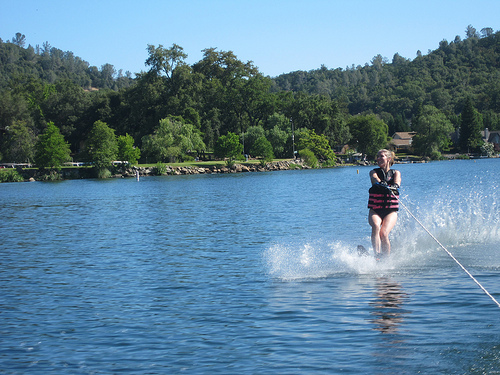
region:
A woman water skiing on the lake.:
[358, 140, 411, 270]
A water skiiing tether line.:
[388, 187, 497, 317]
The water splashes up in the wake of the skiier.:
[261, 231, 368, 281]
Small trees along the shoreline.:
[20, 115, 282, 177]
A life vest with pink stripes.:
[364, 187, 398, 214]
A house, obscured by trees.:
[386, 120, 422, 151]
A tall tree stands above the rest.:
[148, 39, 185, 74]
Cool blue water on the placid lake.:
[15, 185, 202, 301]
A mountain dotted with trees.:
[393, 28, 498, 118]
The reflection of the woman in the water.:
[364, 268, 408, 340]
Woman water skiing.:
[351, 148, 431, 263]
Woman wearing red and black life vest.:
[363, 149, 400, 215]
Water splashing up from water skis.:
[270, 207, 498, 272]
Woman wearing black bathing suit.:
[367, 150, 403, 257]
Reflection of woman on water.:
[370, 270, 410, 343]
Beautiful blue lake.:
[7, 172, 281, 369]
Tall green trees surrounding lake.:
[7, 4, 498, 164]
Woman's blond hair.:
[376, 144, 396, 165]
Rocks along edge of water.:
[142, 159, 312, 175]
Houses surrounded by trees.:
[380, 123, 432, 150]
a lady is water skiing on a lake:
[343, 143, 438, 286]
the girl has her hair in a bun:
[373, 145, 397, 170]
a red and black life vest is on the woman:
[361, 170, 406, 218]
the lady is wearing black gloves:
[373, 176, 403, 196]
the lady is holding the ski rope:
[364, 147, 498, 306]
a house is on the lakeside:
[380, 123, 432, 175]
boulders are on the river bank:
[126, 155, 338, 178]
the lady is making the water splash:
[253, 147, 498, 296]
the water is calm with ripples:
[11, 170, 492, 373]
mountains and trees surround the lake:
[0, 34, 495, 179]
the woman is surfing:
[348, 159, 417, 259]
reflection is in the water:
[361, 279, 427, 353]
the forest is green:
[54, 60, 484, 154]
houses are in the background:
[388, 127, 420, 159]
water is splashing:
[394, 208, 497, 250]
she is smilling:
[350, 130, 409, 268]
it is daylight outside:
[1, 56, 490, 368]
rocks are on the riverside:
[170, 155, 311, 180]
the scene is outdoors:
[6, 8, 488, 373]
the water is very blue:
[1, 158, 498, 371]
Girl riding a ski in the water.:
[331, 135, 411, 280]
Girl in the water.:
[346, 130, 418, 280]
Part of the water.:
[61, 209, 191, 295]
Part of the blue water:
[63, 221, 199, 305]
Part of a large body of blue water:
[56, 218, 183, 298]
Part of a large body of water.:
[64, 217, 206, 299]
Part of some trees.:
[139, 61, 285, 133]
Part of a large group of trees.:
[30, 50, 348, 135]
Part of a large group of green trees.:
[50, 67, 270, 133]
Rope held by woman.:
[373, 175, 498, 295]